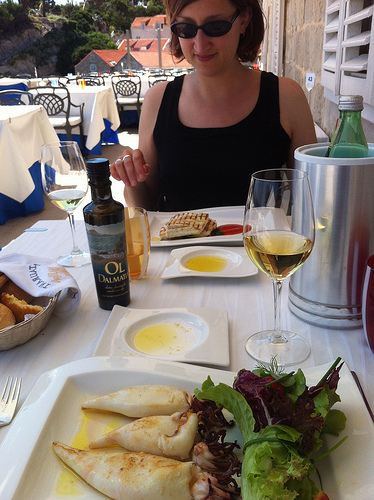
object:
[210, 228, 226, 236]
broccoli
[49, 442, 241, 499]
lobster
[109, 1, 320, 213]
lady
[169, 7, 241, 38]
goggles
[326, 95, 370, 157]
bottle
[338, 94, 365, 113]
top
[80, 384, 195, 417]
chicken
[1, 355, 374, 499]
plate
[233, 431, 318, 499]
greens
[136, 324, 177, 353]
oil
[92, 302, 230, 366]
bowl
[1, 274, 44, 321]
bread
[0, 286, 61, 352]
bowl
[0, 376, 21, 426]
fork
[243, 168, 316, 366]
glass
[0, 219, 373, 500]
table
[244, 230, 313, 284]
wine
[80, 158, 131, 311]
bottle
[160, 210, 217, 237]
grilled cheese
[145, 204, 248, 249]
plate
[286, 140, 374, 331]
bucket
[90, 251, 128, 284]
label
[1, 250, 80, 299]
napkin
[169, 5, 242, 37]
sunglasses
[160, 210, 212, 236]
fish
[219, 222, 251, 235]
red sauce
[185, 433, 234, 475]
squid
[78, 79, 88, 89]
candle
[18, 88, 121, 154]
table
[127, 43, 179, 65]
roof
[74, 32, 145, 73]
house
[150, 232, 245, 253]
edge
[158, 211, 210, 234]
food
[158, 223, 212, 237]
edge